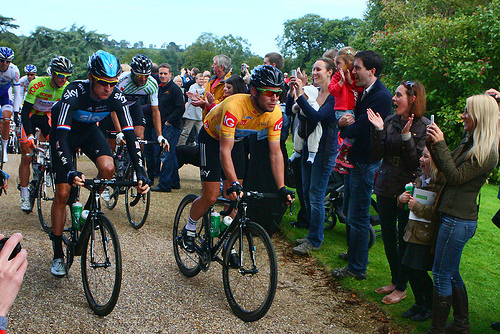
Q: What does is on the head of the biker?
A: A helmet.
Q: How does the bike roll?
A: The wheels.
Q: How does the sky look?
A: Clear.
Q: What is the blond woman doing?
A: Taking a photo.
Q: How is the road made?
A: With dirt.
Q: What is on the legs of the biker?
A: Bike shorts.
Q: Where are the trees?
A: Behind the people.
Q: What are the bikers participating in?
A: Race.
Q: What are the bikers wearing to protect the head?
A: Bike helmets.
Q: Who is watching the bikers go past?
A: Spectators.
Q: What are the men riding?
A: Bicycles.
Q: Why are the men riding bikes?
A: Race.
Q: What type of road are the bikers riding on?
A: Gravel road.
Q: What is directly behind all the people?
A: Trees.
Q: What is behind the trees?
A: Sky.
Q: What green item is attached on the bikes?
A: Water bottles.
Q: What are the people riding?
A: Bicycles.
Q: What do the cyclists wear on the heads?
A: Helmets.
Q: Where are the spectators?
A: On the grass.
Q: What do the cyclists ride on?
A: Gravel.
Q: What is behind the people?
A: Trees.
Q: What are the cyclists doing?
A: Racing.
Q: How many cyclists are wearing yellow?
A: One.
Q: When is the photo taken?
A: Daytime.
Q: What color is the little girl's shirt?
A: Red.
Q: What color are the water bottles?
A: Green.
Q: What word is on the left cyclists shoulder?
A: Sky.